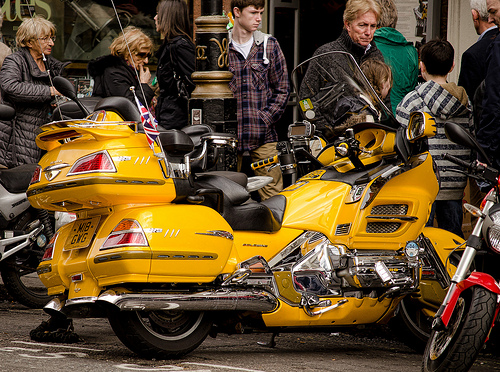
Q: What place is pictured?
A: It is a street.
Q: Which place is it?
A: It is a street.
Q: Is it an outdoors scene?
A: Yes, it is outdoors.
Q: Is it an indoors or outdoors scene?
A: It is outdoors.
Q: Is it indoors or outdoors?
A: It is outdoors.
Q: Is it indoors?
A: No, it is outdoors.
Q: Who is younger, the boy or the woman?
A: The boy is younger than the woman.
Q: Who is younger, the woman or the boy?
A: The boy is younger than the woman.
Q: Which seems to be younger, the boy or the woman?
A: The boy is younger than the woman.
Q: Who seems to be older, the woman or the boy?
A: The woman is older than the boy.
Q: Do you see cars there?
A: No, there are no cars.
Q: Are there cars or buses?
A: No, there are no cars or buses.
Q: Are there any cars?
A: No, there are no cars.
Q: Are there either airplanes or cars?
A: No, there are no cars or airplanes.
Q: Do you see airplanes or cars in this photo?
A: No, there are no cars or airplanes.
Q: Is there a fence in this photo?
A: No, there are no fences.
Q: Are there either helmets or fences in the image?
A: No, there are no fences or helmets.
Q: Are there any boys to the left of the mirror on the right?
A: Yes, there is a boy to the left of the mirror.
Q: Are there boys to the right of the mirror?
A: No, the boy is to the left of the mirror.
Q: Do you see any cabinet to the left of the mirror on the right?
A: No, there is a boy to the left of the mirror.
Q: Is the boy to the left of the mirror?
A: Yes, the boy is to the left of the mirror.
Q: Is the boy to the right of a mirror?
A: No, the boy is to the left of a mirror.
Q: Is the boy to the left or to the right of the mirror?
A: The boy is to the left of the mirror.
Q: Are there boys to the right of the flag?
A: Yes, there is a boy to the right of the flag.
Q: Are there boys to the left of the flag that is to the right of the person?
A: No, the boy is to the right of the flag.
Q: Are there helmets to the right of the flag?
A: No, there is a boy to the right of the flag.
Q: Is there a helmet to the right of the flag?
A: No, there is a boy to the right of the flag.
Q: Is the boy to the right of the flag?
A: Yes, the boy is to the right of the flag.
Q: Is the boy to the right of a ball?
A: No, the boy is to the right of the flag.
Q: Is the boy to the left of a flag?
A: No, the boy is to the right of a flag.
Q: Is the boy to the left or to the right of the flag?
A: The boy is to the right of the flag.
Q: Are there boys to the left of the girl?
A: Yes, there is a boy to the left of the girl.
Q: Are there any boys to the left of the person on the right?
A: Yes, there is a boy to the left of the girl.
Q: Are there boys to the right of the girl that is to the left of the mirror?
A: No, the boy is to the left of the girl.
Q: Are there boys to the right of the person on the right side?
A: No, the boy is to the left of the girl.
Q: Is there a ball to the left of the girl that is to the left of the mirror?
A: No, there is a boy to the left of the girl.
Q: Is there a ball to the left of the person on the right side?
A: No, there is a boy to the left of the girl.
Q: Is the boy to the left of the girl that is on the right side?
A: Yes, the boy is to the left of the girl.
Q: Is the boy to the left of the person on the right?
A: Yes, the boy is to the left of the girl.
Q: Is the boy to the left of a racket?
A: No, the boy is to the left of the girl.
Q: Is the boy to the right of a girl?
A: No, the boy is to the left of a girl.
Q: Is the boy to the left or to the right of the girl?
A: The boy is to the left of the girl.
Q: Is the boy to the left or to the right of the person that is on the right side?
A: The boy is to the left of the girl.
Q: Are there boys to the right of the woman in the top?
A: Yes, there is a boy to the right of the woman.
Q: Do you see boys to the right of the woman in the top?
A: Yes, there is a boy to the right of the woman.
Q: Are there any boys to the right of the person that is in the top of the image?
A: Yes, there is a boy to the right of the woman.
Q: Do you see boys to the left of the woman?
A: No, the boy is to the right of the woman.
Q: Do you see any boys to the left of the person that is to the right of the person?
A: No, the boy is to the right of the woman.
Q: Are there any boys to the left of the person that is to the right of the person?
A: No, the boy is to the right of the woman.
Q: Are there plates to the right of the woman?
A: No, there is a boy to the right of the woman.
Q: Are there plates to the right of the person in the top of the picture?
A: No, there is a boy to the right of the woman.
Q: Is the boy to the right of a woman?
A: Yes, the boy is to the right of a woman.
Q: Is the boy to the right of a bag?
A: No, the boy is to the right of a woman.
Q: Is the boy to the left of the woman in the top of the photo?
A: No, the boy is to the right of the woman.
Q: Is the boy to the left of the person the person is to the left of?
A: No, the boy is to the right of the woman.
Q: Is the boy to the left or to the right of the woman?
A: The boy is to the right of the woman.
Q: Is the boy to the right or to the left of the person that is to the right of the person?
A: The boy is to the right of the woman.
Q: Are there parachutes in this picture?
A: No, there are no parachutes.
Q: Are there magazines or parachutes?
A: No, there are no parachutes or magazines.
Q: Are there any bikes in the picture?
A: Yes, there is a bike.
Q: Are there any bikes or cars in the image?
A: Yes, there is a bike.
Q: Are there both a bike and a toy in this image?
A: No, there is a bike but no toys.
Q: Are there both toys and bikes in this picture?
A: No, there is a bike but no toys.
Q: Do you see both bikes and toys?
A: No, there is a bike but no toys.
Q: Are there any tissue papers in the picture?
A: No, there are no tissue papers.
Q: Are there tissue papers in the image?
A: No, there are no tissue papers.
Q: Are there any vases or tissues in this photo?
A: No, there are no tissues or vases.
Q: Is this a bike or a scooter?
A: This is a bike.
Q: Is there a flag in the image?
A: Yes, there is a flag.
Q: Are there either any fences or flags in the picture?
A: Yes, there is a flag.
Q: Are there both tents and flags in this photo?
A: No, there is a flag but no tents.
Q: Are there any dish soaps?
A: No, there are no dish soaps.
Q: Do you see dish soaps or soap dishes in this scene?
A: No, there are no dish soaps or soap dishes.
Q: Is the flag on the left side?
A: Yes, the flag is on the left of the image.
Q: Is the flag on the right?
A: No, the flag is on the left of the image.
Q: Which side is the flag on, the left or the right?
A: The flag is on the left of the image.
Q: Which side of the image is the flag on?
A: The flag is on the left of the image.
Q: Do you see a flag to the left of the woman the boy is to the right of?
A: Yes, there is a flag to the left of the woman.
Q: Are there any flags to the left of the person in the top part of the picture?
A: Yes, there is a flag to the left of the woman.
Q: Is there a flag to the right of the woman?
A: No, the flag is to the left of the woman.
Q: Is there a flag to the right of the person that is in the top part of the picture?
A: No, the flag is to the left of the woman.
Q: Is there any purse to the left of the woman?
A: No, there is a flag to the left of the woman.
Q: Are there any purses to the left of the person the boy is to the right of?
A: No, there is a flag to the left of the woman.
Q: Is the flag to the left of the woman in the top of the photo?
A: Yes, the flag is to the left of the woman.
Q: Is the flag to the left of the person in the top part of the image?
A: Yes, the flag is to the left of the woman.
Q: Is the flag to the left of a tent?
A: No, the flag is to the left of the woman.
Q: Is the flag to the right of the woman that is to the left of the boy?
A: No, the flag is to the left of the woman.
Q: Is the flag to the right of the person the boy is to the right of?
A: No, the flag is to the left of the woman.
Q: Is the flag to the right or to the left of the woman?
A: The flag is to the left of the woman.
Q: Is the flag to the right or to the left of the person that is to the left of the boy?
A: The flag is to the left of the woman.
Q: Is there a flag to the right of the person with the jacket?
A: Yes, there is a flag to the right of the person.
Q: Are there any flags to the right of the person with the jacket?
A: Yes, there is a flag to the right of the person.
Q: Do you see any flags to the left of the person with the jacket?
A: No, the flag is to the right of the person.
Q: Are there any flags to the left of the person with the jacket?
A: No, the flag is to the right of the person.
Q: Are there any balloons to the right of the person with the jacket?
A: No, there is a flag to the right of the person.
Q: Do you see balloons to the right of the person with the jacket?
A: No, there is a flag to the right of the person.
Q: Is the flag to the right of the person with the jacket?
A: Yes, the flag is to the right of the person.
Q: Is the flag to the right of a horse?
A: No, the flag is to the right of the person.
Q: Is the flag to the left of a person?
A: No, the flag is to the right of a person.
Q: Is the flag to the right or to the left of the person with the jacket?
A: The flag is to the right of the person.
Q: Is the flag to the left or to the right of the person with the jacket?
A: The flag is to the right of the person.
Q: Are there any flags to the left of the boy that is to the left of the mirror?
A: Yes, there is a flag to the left of the boy.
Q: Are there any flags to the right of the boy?
A: No, the flag is to the left of the boy.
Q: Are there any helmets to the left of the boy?
A: No, there is a flag to the left of the boy.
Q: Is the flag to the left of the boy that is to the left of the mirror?
A: Yes, the flag is to the left of the boy.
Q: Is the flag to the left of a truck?
A: No, the flag is to the left of the boy.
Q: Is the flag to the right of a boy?
A: No, the flag is to the left of a boy.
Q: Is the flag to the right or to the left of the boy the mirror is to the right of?
A: The flag is to the left of the boy.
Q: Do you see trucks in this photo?
A: No, there are no trucks.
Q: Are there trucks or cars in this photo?
A: No, there are no trucks or cars.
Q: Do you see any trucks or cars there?
A: No, there are no trucks or cars.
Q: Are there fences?
A: No, there are no fences.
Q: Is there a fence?
A: No, there are no fences.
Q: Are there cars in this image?
A: No, there are no cars.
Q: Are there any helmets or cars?
A: No, there are no cars or helmets.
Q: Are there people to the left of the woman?
A: Yes, there is a person to the left of the woman.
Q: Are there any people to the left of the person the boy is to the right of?
A: Yes, there is a person to the left of the woman.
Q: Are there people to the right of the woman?
A: No, the person is to the left of the woman.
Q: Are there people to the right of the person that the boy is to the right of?
A: No, the person is to the left of the woman.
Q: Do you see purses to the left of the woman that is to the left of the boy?
A: No, there is a person to the left of the woman.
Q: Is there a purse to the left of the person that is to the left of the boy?
A: No, there is a person to the left of the woman.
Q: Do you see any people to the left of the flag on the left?
A: Yes, there is a person to the left of the flag.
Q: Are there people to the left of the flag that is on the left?
A: Yes, there is a person to the left of the flag.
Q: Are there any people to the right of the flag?
A: No, the person is to the left of the flag.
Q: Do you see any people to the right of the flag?
A: No, the person is to the left of the flag.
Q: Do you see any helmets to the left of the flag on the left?
A: No, there is a person to the left of the flag.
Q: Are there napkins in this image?
A: No, there are no napkins.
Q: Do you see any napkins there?
A: No, there are no napkins.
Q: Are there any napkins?
A: No, there are no napkins.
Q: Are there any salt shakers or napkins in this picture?
A: No, there are no napkins or salt shakers.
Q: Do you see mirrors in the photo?
A: Yes, there is a mirror.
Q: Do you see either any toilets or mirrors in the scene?
A: Yes, there is a mirror.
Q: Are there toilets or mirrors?
A: Yes, there is a mirror.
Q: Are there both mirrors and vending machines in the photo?
A: No, there is a mirror but no vending machines.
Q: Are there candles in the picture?
A: No, there are no candles.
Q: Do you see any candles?
A: No, there are no candles.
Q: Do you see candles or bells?
A: No, there are no candles or bells.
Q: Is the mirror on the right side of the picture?
A: Yes, the mirror is on the right of the image.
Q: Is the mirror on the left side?
A: No, the mirror is on the right of the image.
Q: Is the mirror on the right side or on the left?
A: The mirror is on the right of the image.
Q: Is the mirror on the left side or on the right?
A: The mirror is on the right of the image.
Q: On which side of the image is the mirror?
A: The mirror is on the right of the image.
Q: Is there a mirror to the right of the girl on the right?
A: Yes, there is a mirror to the right of the girl.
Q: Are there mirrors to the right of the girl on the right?
A: Yes, there is a mirror to the right of the girl.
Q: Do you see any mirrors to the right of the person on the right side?
A: Yes, there is a mirror to the right of the girl.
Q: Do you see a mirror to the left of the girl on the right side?
A: No, the mirror is to the right of the girl.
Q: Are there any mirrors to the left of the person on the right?
A: No, the mirror is to the right of the girl.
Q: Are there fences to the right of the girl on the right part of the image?
A: No, there is a mirror to the right of the girl.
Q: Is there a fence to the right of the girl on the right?
A: No, there is a mirror to the right of the girl.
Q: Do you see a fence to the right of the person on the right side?
A: No, there is a mirror to the right of the girl.